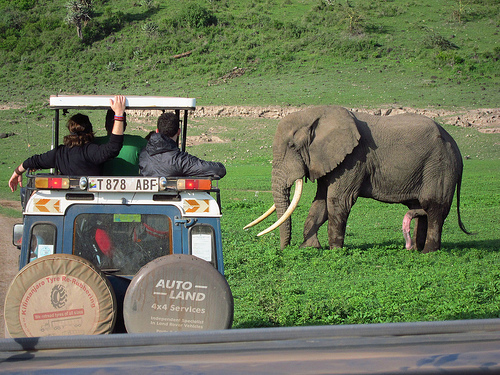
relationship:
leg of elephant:
[418, 152, 458, 253] [238, 103, 483, 260]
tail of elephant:
[455, 177, 473, 235] [238, 103, 483, 260]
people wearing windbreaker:
[8, 95, 126, 192] [137, 129, 226, 178]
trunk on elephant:
[267, 147, 298, 254] [238, 103, 483, 260]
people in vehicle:
[10, 90, 227, 187] [11, 77, 238, 340]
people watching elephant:
[10, 90, 227, 187] [238, 103, 483, 260]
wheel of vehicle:
[112, 236, 242, 346] [11, 77, 238, 340]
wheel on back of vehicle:
[4, 254, 117, 339] [18, 93, 226, 338]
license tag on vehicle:
[79, 171, 169, 194] [15, 64, 275, 366]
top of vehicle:
[48, 90, 198, 111] [19, 95, 239, 351]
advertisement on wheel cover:
[149, 273, 212, 309] [115, 246, 245, 344]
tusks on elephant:
[239, 194, 346, 246] [249, 110, 479, 245]